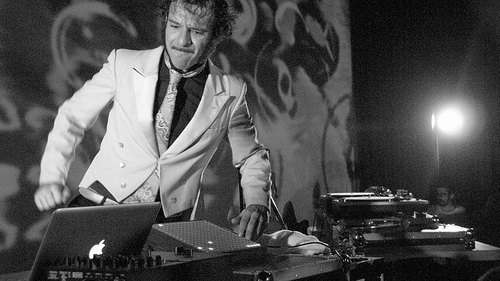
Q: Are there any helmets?
A: No, there are no helmets.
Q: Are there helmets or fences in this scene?
A: No, there are no helmets or fences.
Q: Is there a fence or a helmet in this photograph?
A: No, there are no helmets or fences.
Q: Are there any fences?
A: No, there are no fences.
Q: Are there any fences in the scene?
A: No, there are no fences.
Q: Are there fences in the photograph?
A: No, there are no fences.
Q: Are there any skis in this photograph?
A: No, there are no skis.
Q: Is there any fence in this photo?
A: No, there are no fences.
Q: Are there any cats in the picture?
A: No, there are no cats.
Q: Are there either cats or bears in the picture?
A: No, there are no cats or bears.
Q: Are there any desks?
A: Yes, there is a desk.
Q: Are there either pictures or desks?
A: Yes, there is a desk.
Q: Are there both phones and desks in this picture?
A: No, there is a desk but no phones.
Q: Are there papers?
A: No, there are no papers.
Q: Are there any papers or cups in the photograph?
A: No, there are no papers or cups.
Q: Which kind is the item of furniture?
A: The piece of furniture is a desk.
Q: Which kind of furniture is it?
A: The piece of furniture is a desk.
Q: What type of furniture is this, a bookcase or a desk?
A: That is a desk.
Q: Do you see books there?
A: No, there are no books.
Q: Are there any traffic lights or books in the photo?
A: No, there are no books or traffic lights.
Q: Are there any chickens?
A: No, there are no chickens.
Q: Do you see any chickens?
A: No, there are no chickens.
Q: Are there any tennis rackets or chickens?
A: No, there are no chickens or tennis rackets.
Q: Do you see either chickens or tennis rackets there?
A: No, there are no chickens or tennis rackets.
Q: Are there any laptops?
A: Yes, there is a laptop.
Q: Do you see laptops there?
A: Yes, there is a laptop.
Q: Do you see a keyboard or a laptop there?
A: Yes, there is a laptop.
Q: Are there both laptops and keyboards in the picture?
A: No, there is a laptop but no keyboards.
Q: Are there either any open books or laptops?
A: Yes, there is an open laptop.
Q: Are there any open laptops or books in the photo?
A: Yes, there is an open laptop.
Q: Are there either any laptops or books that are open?
A: Yes, the laptop is open.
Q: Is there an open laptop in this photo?
A: Yes, there is an open laptop.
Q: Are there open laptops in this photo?
A: Yes, there is an open laptop.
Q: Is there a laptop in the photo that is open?
A: Yes, there is a laptop that is open.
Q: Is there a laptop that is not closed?
A: Yes, there is a open laptop.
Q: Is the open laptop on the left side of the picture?
A: Yes, the laptop is on the left of the image.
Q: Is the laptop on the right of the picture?
A: No, the laptop is on the left of the image.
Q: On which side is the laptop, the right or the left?
A: The laptop is on the left of the image.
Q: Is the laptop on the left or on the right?
A: The laptop is on the left of the image.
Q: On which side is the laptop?
A: The laptop is on the left of the image.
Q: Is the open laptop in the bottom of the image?
A: Yes, the laptop is in the bottom of the image.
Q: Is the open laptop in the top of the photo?
A: No, the laptop computer is in the bottom of the image.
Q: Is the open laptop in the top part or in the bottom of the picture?
A: The laptop is in the bottom of the image.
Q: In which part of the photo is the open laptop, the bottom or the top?
A: The laptop is in the bottom of the image.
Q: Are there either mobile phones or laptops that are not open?
A: No, there is a laptop but it is open.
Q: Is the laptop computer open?
A: Yes, the laptop computer is open.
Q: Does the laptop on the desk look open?
A: Yes, the laptop computer is open.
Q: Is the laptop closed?
A: No, the laptop is open.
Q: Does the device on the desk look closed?
A: No, the laptop is open.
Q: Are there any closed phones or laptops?
A: No, there is a laptop but it is open.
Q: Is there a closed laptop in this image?
A: No, there is a laptop but it is open.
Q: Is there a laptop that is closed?
A: No, there is a laptop but it is open.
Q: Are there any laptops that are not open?
A: No, there is a laptop but it is open.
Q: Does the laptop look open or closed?
A: The laptop is open.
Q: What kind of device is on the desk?
A: The device is a laptop.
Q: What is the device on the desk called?
A: The device is a laptop.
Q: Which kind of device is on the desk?
A: The device is a laptop.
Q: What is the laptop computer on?
A: The laptop computer is on the desk.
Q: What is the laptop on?
A: The laptop computer is on the desk.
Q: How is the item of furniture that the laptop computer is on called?
A: The piece of furniture is a desk.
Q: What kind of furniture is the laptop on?
A: The laptop computer is on the desk.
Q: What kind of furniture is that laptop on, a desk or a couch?
A: The laptop is on a desk.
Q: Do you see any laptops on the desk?
A: Yes, there is a laptop on the desk.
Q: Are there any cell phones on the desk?
A: No, there is a laptop on the desk.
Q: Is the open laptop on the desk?
A: Yes, the laptop computer is on the desk.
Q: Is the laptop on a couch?
A: No, the laptop is on the desk.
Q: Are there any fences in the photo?
A: No, there are no fences.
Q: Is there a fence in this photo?
A: No, there are no fences.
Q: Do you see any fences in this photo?
A: No, there are no fences.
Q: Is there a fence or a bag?
A: No, there are no fences or bags.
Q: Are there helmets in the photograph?
A: No, there are no helmets.